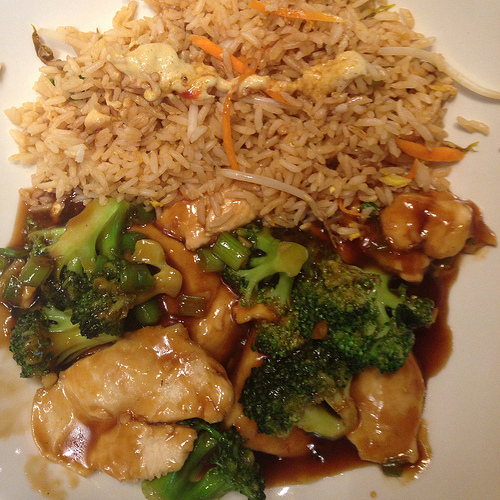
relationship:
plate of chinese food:
[1, 1, 500, 499] [3, 1, 500, 497]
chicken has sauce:
[380, 193, 472, 261] [3, 190, 497, 498]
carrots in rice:
[189, 30, 295, 167] [7, 3, 486, 226]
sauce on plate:
[3, 190, 497, 498] [1, 1, 500, 499]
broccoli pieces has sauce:
[3, 198, 163, 374] [3, 190, 497, 498]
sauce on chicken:
[3, 190, 497, 498] [380, 193, 472, 261]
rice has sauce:
[7, 3, 486, 226] [3, 190, 497, 498]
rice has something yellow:
[7, 3, 486, 226] [376, 172, 414, 192]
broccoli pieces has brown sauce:
[3, 198, 163, 374] [3, 190, 497, 498]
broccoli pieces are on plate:
[3, 198, 163, 374] [1, 1, 500, 499]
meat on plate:
[124, 45, 375, 113] [1, 1, 500, 499]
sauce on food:
[3, 190, 497, 498] [3, 1, 500, 497]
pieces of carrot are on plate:
[393, 131, 466, 182] [1, 1, 500, 499]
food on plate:
[3, 1, 500, 497] [1, 1, 500, 499]